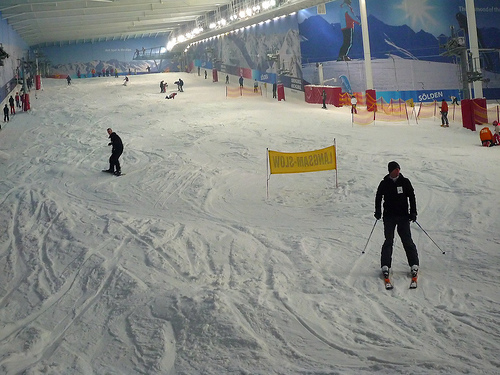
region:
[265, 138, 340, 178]
Yellow sign at indoor skiing event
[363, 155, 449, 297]
Man in a black jacket skiing indoors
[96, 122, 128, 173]
Man in a black jacket snowboarding indoors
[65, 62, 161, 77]
People at the top of the slope waiting to ski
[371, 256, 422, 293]
Skis turned slightly inward to slow down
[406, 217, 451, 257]
Skiing pole being held by a man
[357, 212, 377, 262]
Skiing pole being held by a man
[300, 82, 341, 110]
Red barrier next to the wall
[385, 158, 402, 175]
Black bennie being used by a skier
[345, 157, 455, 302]
person skiing on snow covered hill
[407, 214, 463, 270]
ski pole in skier's hand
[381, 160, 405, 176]
black hat on skier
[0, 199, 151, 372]
ski trail on snow slope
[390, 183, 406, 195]
white square on front of black winter coat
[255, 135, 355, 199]
yellow banner on snow slope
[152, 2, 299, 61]
white lights at top of interor snow slope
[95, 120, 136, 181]
person snowboarding down hill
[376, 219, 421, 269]
pair of black snow pants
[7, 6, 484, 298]
people are skiing and snowboarding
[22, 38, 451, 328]
people skiing and snowboarding indoors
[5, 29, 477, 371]
this is an indoor ski slope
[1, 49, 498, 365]
the snow is indoors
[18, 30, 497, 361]
a ski slope inside a building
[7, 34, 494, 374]
a ski slope inside a room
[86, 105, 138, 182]
he is snowboarding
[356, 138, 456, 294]
he is skiing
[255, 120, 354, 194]
this is a yellow sign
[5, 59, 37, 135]
they are lined up to ski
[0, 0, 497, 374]
inside snowy ski slope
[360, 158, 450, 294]
a man on skis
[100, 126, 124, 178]
a person snowboarding down slope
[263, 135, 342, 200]
the backside of a yellow sign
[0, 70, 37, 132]
people moving up the slope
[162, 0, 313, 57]
lights along upper side of wall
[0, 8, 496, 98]
winter scenes on the walls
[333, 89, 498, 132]
yellow mesh fence on side of slope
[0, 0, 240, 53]
white ceiling of building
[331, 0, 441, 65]
large picture of person and sun on the wall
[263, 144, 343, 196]
the sign is yellow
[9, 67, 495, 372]
ski marks in the snow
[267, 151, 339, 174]
black letters on sign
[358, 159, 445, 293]
man holding ski poles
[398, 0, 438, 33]
sun painted on wall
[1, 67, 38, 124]
people standing beside wall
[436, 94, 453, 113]
person's shirt is red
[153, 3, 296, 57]
the lights are white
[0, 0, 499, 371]
people are skiing indoors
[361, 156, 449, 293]
person wearing a hat